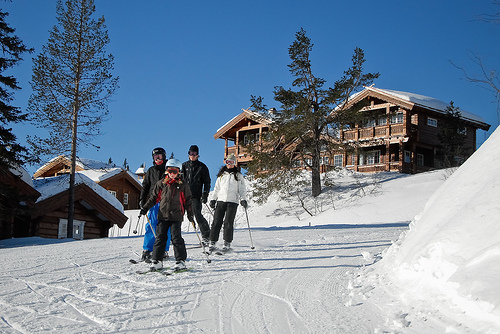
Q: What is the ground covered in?
A: Snow.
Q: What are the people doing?
A: Skiing.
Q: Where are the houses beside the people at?
A: On the left side of the shot.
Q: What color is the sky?
A: Blue.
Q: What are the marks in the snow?
A: Ski tracks.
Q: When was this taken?
A: Winter.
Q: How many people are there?
A: 4.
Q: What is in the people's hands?
A: Ski poles.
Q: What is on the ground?
A: Snow.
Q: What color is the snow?
A: White.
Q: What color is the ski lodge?
A: Brown.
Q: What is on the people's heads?
A: Hats.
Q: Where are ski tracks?
A: On the snow.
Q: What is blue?
A: Sky.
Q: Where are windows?
A: On a building.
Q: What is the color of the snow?
A: Crystal white.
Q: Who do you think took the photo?
A: I think the photographer.